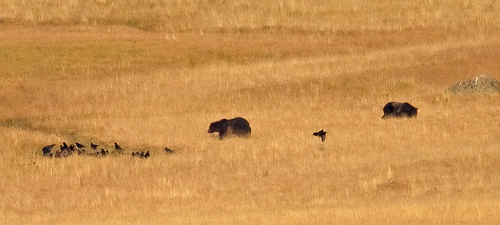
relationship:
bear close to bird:
[381, 102, 418, 119] [160, 145, 173, 155]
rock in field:
[444, 74, 499, 96] [0, 0, 498, 222]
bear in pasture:
[381, 97, 418, 119] [6, 10, 484, 212]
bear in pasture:
[205, 113, 254, 138] [6, 10, 484, 212]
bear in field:
[207, 116, 253, 141] [0, 0, 498, 222]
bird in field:
[312, 130, 326, 142] [0, 0, 498, 222]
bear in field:
[381, 102, 418, 119] [0, 0, 498, 222]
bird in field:
[163, 146, 173, 153] [0, 0, 498, 222]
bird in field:
[113, 140, 122, 152] [0, 0, 498, 222]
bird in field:
[40, 142, 57, 154] [0, 0, 498, 222]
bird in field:
[75, 141, 86, 148] [0, 0, 498, 222]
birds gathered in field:
[164, 146, 174, 154] [21, 44, 180, 126]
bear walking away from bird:
[381, 102, 418, 119] [161, 141, 178, 156]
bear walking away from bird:
[381, 102, 418, 119] [108, 137, 124, 152]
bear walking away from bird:
[381, 102, 418, 119] [86, 140, 99, 152]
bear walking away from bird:
[381, 102, 418, 119] [74, 136, 86, 152]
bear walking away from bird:
[381, 102, 418, 119] [56, 139, 68, 152]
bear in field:
[381, 102, 418, 119] [8, 62, 489, 184]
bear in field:
[205, 113, 254, 138] [8, 62, 489, 184]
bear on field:
[207, 116, 253, 141] [0, 0, 498, 222]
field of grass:
[1, 54, 499, 221] [12, 38, 493, 223]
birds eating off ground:
[164, 146, 174, 154] [3, 2, 498, 222]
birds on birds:
[161, 144, 175, 155] [111, 141, 122, 149]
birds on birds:
[161, 144, 175, 155] [87, 137, 99, 148]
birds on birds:
[161, 144, 175, 155] [41, 142, 56, 151]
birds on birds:
[161, 144, 175, 155] [73, 140, 88, 148]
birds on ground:
[161, 144, 175, 155] [3, 2, 498, 222]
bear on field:
[381, 102, 418, 119] [0, 0, 498, 222]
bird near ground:
[312, 125, 329, 139] [3, 2, 498, 222]